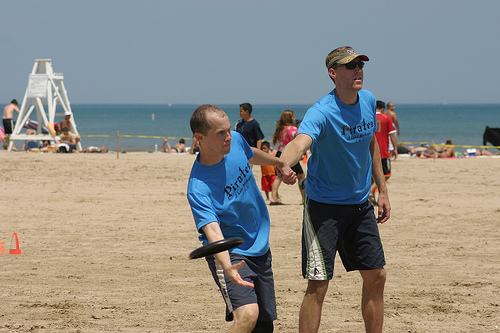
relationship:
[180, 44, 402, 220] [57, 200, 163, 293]
two men at beach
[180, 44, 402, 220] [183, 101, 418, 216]
two men wearing same shirt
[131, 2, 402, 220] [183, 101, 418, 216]
two men wearing blue shirt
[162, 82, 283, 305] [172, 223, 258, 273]
man throwing frisbee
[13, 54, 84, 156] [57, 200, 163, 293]
chair chair at beach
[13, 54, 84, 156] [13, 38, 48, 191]
chair lifeguard chair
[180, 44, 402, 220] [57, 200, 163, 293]
two men enjoying beach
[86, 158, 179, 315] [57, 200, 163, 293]
sand on beach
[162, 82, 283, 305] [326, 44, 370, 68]
man wearing a cap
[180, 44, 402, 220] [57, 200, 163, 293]
two men playing at beach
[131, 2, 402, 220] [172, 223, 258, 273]
two men playing frisbee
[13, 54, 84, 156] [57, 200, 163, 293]
chair tower on beach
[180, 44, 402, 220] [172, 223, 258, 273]
two men playing frisbee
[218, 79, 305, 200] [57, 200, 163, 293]
family on beach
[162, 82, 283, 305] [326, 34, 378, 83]
man on beach with cap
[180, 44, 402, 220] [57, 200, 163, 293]
two men walking on beach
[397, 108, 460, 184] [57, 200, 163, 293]
people sun bathing at beach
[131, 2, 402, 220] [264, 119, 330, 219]
two men holding hands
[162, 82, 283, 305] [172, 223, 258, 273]
man throwing black frisbee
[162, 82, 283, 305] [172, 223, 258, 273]
man catching frisbee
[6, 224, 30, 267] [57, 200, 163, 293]
orange cone on beach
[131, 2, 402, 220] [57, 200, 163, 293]
two men on beach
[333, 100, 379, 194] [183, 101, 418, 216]
blue tee shirt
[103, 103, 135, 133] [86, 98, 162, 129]
ocean in background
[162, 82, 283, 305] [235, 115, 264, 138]
man in black tee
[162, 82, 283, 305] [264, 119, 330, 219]
man holding hands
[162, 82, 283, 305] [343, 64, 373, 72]
man wearing sunglasses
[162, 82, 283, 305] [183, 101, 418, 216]
man wearing red shirt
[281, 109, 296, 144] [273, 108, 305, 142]
woman wearing pink shirt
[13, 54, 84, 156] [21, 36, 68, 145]
chair chair white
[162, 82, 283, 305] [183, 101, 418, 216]
man wearing shirts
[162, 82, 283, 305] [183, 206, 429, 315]
man wearing shorts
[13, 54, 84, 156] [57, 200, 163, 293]
chair chair on beach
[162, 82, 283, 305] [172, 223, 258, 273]
man playing frisbee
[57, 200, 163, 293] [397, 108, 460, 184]
beach full of people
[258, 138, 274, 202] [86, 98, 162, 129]
boy in background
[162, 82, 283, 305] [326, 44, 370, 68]
man with cap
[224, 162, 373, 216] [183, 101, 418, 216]
name of team on shirt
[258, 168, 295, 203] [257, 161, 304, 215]
boy in shorts